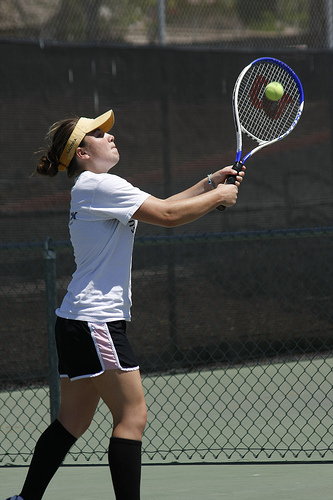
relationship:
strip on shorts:
[85, 321, 123, 374] [52, 168, 149, 381]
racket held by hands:
[224, 55, 306, 201] [210, 153, 251, 207]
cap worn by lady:
[21, 98, 138, 165] [8, 108, 245, 497]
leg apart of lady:
[93, 354, 175, 499] [41, 109, 165, 365]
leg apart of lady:
[90, 368, 148, 498] [8, 108, 245, 497]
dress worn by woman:
[57, 167, 145, 377] [20, 114, 158, 493]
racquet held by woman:
[218, 55, 306, 209] [3, 108, 247, 499]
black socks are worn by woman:
[107, 437, 142, 498] [3, 108, 247, 499]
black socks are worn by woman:
[19, 417, 77, 498] [3, 108, 247, 499]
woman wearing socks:
[3, 108, 247, 499] [19, 417, 142, 499]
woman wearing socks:
[3, 108, 247, 499] [106, 433, 145, 498]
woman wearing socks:
[3, 108, 247, 499] [17, 418, 76, 498]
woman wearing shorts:
[3, 108, 247, 499] [52, 312, 142, 383]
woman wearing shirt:
[3, 108, 247, 499] [54, 169, 152, 321]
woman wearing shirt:
[40, 80, 167, 341] [54, 169, 152, 321]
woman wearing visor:
[3, 108, 247, 499] [54, 108, 114, 173]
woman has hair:
[3, 108, 247, 499] [32, 104, 70, 175]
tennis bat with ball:
[215, 53, 308, 213] [264, 75, 286, 104]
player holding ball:
[6, 113, 247, 498] [263, 80, 282, 99]